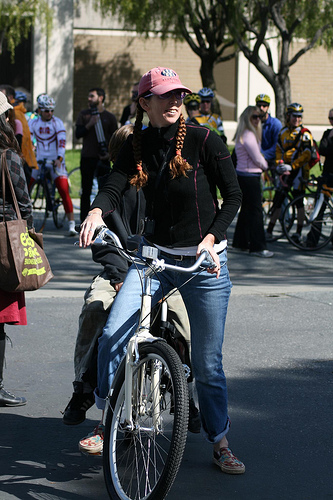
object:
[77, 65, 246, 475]
person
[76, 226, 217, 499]
bicycle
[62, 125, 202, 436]
person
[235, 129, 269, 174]
sweater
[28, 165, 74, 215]
pants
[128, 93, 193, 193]
hair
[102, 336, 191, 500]
wheel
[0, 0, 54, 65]
trees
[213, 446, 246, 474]
left foot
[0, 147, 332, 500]
ground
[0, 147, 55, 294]
bag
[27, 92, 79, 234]
man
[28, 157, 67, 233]
bike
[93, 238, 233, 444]
jeans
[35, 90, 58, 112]
helmet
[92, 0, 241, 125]
tree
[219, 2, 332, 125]
tree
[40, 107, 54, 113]
sunglasses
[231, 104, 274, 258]
people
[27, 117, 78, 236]
outfit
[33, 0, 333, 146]
building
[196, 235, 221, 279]
hand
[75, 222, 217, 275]
handlebar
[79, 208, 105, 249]
hand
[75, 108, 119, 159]
clothes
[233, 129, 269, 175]
top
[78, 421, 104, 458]
shoe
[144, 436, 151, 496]
spoke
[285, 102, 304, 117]
helmet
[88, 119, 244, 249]
shirt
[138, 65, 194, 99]
cap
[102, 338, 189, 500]
tire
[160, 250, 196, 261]
belt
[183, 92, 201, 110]
helmet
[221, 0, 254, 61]
branch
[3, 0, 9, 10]
leaves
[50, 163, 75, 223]
leg